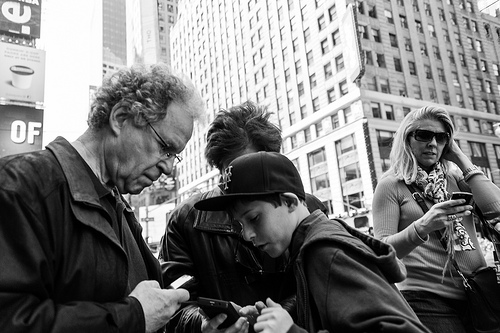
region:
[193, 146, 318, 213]
A black baseball hat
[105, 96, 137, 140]
The right ear of the person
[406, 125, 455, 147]
A black sunglasses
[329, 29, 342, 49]
A window on the building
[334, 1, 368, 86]
A sign hanging on the building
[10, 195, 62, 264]
Part of the person's jacket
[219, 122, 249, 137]
Part of the person's hair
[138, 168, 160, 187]
The mouth of the person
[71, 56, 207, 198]
The head of the person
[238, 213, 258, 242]
The nose of the person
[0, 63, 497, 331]
the people standing outside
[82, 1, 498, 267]
the building behind the people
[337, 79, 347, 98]
the window of the building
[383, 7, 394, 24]
the window of the building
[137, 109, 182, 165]
the glasses on the man's face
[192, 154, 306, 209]
the hat on the boy's head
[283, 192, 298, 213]
the ear on the boy's head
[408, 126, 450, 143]
the glasses on the woman's face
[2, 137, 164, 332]
the jacket on the man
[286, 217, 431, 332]
the jacket on the boy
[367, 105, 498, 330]
lady looking at her cell phone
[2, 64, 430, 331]
the males looking at a cell phone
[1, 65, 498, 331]
four people all looking at cell phones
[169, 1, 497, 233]
sky scraper in a big city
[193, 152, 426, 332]
kid in baseball cap looking at cell phone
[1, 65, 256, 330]
man with curly hair looking at cell phone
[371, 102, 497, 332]
woman in sun glasses looking at cell phone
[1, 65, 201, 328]
man in glasses holding a cell phone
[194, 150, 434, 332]
young male looking at cell phone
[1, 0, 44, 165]
ad on the side of the building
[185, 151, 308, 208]
this is a hat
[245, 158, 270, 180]
the hat is black in color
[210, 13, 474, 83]
this is a building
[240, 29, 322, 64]
the building has windows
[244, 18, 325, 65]
the windows are closed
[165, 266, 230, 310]
these are mobile phones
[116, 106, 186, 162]
this is a pair of spectacles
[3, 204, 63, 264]
the jacket is black in color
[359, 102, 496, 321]
this is a woman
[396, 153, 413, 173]
the hair is blonde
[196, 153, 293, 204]
boy is wearing a hat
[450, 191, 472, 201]
women holding a cellphone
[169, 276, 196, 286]
man holding a cellphone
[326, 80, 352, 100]
windows in the building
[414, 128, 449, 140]
women wearing sunglasses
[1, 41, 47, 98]
a banner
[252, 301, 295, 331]
the boys hands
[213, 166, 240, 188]
logo on the hat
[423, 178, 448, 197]
women is wearing a scarf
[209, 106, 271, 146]
a persons hair